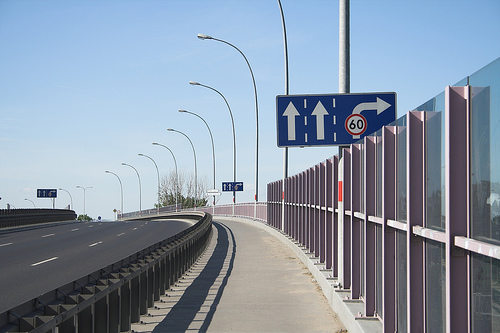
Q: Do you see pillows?
A: No, there are no pillows.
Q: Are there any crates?
A: No, there are no crates.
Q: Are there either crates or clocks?
A: No, there are no crates or clocks.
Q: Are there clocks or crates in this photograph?
A: No, there are no crates or clocks.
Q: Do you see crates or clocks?
A: No, there are no crates or clocks.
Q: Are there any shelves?
A: No, there are no shelves.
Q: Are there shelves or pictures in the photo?
A: No, there are no shelves or pictures.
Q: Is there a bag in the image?
A: No, there are no bags.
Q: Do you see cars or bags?
A: No, there are no bags or cars.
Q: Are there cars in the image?
A: No, there are no cars.